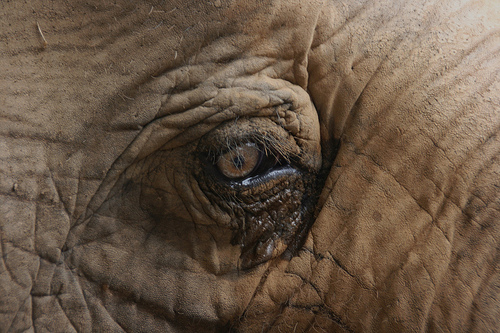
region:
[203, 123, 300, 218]
it is the eye of the elephant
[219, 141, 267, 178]
the eye has a hazel color to it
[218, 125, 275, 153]
eyelashes of the elephant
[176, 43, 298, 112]
wrinkles on the elephants face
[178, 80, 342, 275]
it is an elephants eyeball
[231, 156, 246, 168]
it is the pupil of the elephant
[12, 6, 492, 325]
it is the eye of a big elephant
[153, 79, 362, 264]
an animals eye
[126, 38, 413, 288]
grey elephant with brown eye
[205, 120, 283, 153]
thin eye lashes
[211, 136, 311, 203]
eye of the elephant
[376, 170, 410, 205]
wrinkle of the elephant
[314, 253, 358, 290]
wrinkle of the elephant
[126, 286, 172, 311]
wrinkle of the elephant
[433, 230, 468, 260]
wrinkle of the elephant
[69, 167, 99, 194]
wrinkle of the elephant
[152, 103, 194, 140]
wrinkle of the elephant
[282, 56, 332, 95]
wrinkle of the elephant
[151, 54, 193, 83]
wrinkle of the elephant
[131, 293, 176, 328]
wrinkle of the elephant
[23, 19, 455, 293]
this is an elephant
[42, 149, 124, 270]
the elephant's skin is wrinkled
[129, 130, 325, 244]
this is the elephant's eye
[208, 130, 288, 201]
the eye is yellow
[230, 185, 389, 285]
there is fluid around the eye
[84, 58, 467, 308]
the elephant's skin is gray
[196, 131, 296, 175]
these are eyelashes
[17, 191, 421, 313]
the elephant's skin is cracked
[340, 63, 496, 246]
the elephant has a tint of brown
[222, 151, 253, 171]
the pupil is black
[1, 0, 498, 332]
The eye of an elephant.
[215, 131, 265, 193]
a eye of elephants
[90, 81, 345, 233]
a wrinkle around th eeyes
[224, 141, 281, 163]
eyelashes on a eye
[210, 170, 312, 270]
wetness under the ear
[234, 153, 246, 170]
a black puple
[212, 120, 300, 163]
a brown eye lid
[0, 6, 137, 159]
brown wrinkly skin on a elephant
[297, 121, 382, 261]
a crease in the eye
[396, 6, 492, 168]
black dot on the skin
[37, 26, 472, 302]
a eye of elephant crying